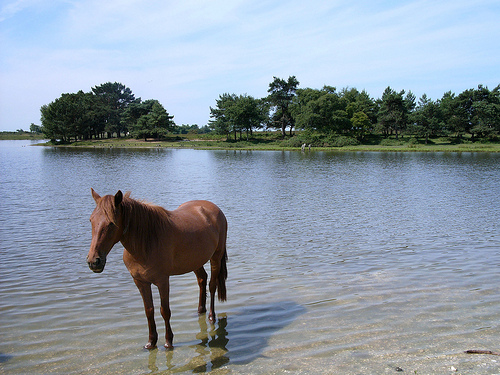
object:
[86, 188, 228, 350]
horse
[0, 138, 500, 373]
water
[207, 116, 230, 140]
tree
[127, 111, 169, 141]
tree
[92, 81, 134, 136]
tree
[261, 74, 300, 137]
tree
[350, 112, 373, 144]
tree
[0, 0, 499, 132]
sky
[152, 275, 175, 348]
leg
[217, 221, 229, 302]
tail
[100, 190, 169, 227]
mane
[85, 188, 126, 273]
head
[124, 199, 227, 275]
body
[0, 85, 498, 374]
area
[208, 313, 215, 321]
hoof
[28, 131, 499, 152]
land